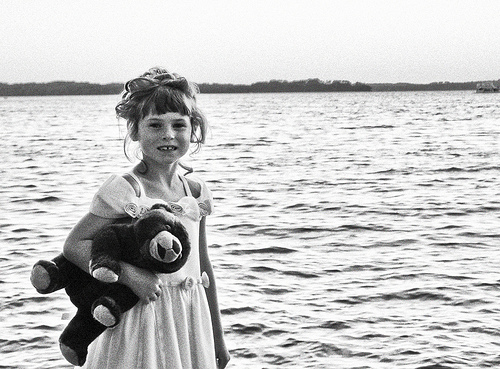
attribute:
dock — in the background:
[475, 79, 498, 94]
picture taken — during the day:
[42, 77, 331, 310]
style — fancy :
[94, 71, 241, 153]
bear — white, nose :
[15, 213, 206, 363]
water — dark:
[1, 94, 498, 367]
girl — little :
[52, 48, 256, 366]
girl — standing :
[67, 64, 230, 367]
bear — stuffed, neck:
[32, 201, 185, 367]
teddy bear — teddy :
[0, 202, 209, 356]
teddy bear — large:
[55, 179, 225, 331]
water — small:
[223, 87, 490, 354]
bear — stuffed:
[25, 204, 198, 345]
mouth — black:
[147, 238, 171, 265]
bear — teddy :
[45, 210, 189, 352]